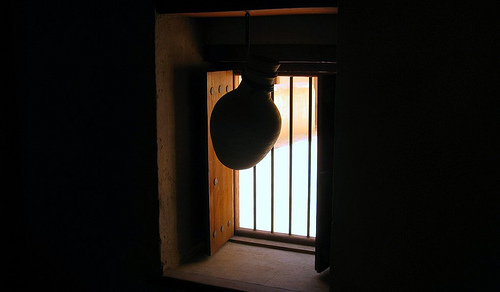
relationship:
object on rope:
[209, 51, 287, 174] [235, 16, 262, 57]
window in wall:
[238, 72, 319, 244] [3, 3, 500, 285]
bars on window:
[233, 75, 318, 244] [238, 72, 319, 244]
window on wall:
[238, 72, 319, 244] [3, 3, 500, 285]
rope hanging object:
[235, 16, 262, 57] [209, 51, 287, 174]